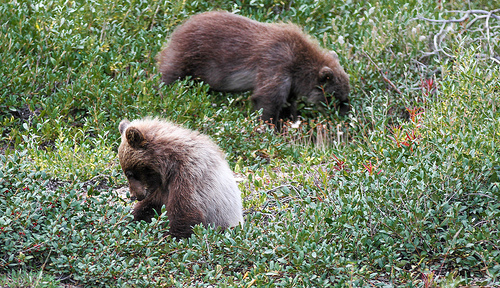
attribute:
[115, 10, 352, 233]
two baby bears — young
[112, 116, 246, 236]
bear baby — bent over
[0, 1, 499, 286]
green vegetation — bright green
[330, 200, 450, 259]
plants — yellowish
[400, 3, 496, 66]
plant — bare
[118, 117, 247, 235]
bear — brown, light brown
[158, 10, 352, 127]
bear — brown, dark brown